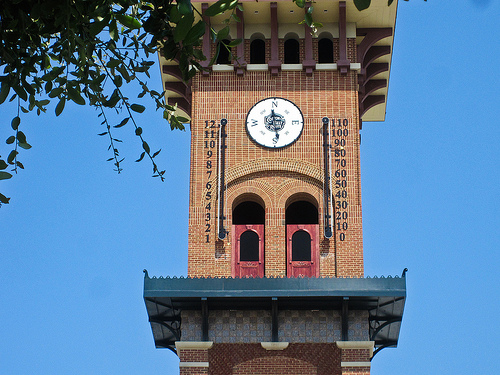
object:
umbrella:
[142, 268, 408, 363]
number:
[340, 233, 345, 242]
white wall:
[210, 323, 271, 341]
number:
[332, 119, 349, 128]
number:
[207, 150, 214, 159]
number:
[335, 201, 347, 209]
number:
[334, 180, 347, 189]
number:
[205, 234, 211, 244]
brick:
[196, 90, 245, 118]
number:
[335, 159, 347, 168]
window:
[231, 192, 266, 226]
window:
[284, 191, 319, 225]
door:
[287, 224, 320, 278]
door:
[232, 224, 265, 279]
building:
[142, 0, 409, 375]